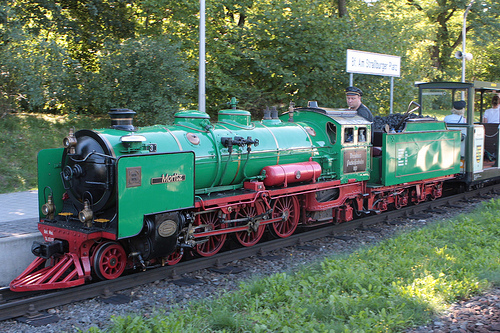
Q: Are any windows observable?
A: Yes, there is a window.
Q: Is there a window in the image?
A: Yes, there is a window.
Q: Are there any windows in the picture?
A: Yes, there is a window.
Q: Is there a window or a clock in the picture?
A: Yes, there is a window.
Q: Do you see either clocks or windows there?
A: Yes, there is a window.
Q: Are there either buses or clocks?
A: No, there are no buses or clocks.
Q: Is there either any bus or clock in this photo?
A: No, there are no buses or clocks.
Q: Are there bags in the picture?
A: No, there are no bags.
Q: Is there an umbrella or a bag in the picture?
A: No, there are no bags or umbrellas.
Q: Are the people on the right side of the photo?
A: Yes, the people are on the right of the image.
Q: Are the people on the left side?
A: No, the people are on the right of the image.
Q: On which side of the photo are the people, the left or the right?
A: The people are on the right of the image.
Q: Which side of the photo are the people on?
A: The people are on the right of the image.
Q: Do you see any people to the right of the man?
A: Yes, there are people to the right of the man.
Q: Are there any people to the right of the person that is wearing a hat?
A: Yes, there are people to the right of the man.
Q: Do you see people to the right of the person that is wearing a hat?
A: Yes, there are people to the right of the man.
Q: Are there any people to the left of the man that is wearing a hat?
A: No, the people are to the right of the man.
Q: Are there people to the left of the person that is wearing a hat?
A: No, the people are to the right of the man.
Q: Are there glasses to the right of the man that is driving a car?
A: No, there are people to the right of the man.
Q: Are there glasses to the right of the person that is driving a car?
A: No, there are people to the right of the man.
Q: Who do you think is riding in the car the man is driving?
A: The people are riding in the car.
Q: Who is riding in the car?
A: The people are riding in the car.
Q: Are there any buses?
A: No, there are no buses.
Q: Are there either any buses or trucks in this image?
A: No, there are no buses or trucks.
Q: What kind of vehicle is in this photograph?
A: The vehicle is a car.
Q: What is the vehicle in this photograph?
A: The vehicle is a car.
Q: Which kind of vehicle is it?
A: The vehicle is a car.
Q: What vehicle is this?
A: That is a car.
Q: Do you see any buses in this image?
A: No, there are no buses.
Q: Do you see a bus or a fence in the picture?
A: No, there are no buses or fences.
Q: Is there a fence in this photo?
A: No, there are no fences.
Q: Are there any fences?
A: No, there are no fences.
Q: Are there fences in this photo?
A: No, there are no fences.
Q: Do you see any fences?
A: No, there are no fences.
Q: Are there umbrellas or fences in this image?
A: No, there are no fences or umbrellas.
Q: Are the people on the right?
A: Yes, the people are on the right of the image.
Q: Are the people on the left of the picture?
A: No, the people are on the right of the image.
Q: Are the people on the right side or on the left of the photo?
A: The people are on the right of the image.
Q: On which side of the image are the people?
A: The people are on the right of the image.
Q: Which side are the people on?
A: The people are on the right of the image.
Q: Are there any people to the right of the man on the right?
A: Yes, there are people to the right of the man.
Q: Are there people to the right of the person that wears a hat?
A: Yes, there are people to the right of the man.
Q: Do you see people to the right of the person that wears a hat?
A: Yes, there are people to the right of the man.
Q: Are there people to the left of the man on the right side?
A: No, the people are to the right of the man.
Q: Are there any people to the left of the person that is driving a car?
A: No, the people are to the right of the man.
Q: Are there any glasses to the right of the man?
A: No, there are people to the right of the man.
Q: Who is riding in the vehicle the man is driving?
A: The people are riding in the car.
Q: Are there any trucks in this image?
A: No, there are no trucks.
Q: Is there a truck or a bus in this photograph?
A: No, there are no trucks or buses.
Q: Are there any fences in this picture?
A: No, there are no fences.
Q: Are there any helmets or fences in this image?
A: No, there are no fences or helmets.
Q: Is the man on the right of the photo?
A: Yes, the man is on the right of the image.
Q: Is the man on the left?
A: No, the man is on the right of the image.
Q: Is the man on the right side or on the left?
A: The man is on the right of the image.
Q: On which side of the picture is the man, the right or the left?
A: The man is on the right of the image.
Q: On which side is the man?
A: The man is on the right of the image.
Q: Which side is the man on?
A: The man is on the right of the image.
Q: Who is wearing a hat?
A: The man is wearing a hat.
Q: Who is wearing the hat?
A: The man is wearing a hat.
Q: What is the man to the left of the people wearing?
A: The man is wearing a hat.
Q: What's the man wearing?
A: The man is wearing a hat.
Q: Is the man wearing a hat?
A: Yes, the man is wearing a hat.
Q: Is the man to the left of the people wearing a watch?
A: No, the man is wearing a hat.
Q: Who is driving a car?
A: The man is driving a car.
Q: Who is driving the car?
A: The man is driving a car.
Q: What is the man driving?
A: The man is driving a car.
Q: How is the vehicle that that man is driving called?
A: The vehicle is a car.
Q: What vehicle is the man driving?
A: The man is driving a car.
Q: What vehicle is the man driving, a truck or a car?
A: The man is driving a car.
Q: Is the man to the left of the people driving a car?
A: Yes, the man is driving a car.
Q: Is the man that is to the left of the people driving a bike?
A: No, the man is driving a car.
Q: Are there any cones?
A: No, there are no cones.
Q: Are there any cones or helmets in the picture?
A: No, there are no cones or helmets.